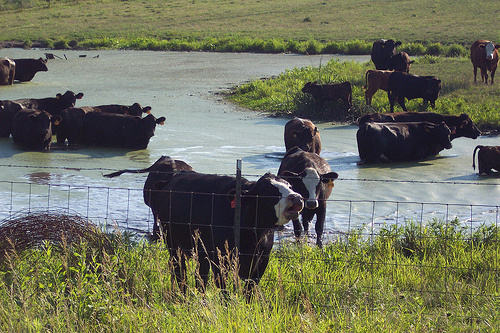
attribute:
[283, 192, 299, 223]
mouth — open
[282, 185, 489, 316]
wire — barbed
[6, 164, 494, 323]
fence — mesh, barbed wire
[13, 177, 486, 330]
wire — barbed, rusty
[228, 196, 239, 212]
tag — red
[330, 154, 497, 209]
wire — barbed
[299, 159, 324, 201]
stripe — thick, white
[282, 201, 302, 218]
mouth — cow's, open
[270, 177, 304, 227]
face — white